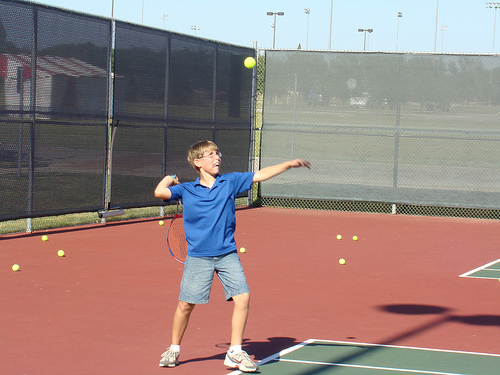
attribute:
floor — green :
[218, 342, 498, 372]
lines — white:
[275, 329, 344, 372]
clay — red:
[254, 277, 338, 306]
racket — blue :
[163, 173, 197, 265]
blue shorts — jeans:
[173, 243, 251, 310]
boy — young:
[152, 140, 309, 373]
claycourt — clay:
[1, 204, 499, 373]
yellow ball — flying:
[242, 57, 257, 71]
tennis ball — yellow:
[41, 232, 49, 242]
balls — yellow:
[9, 217, 359, 272]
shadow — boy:
[177, 332, 372, 373]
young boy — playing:
[150, 139, 312, 372]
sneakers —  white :
[155, 348, 260, 373]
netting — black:
[240, 33, 487, 196]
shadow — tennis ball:
[348, 329, 356, 345]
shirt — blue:
[170, 176, 251, 254]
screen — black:
[9, 10, 173, 166]